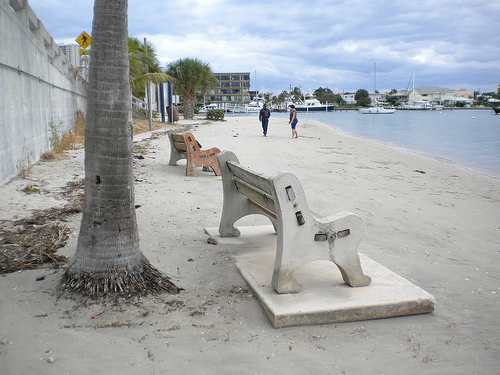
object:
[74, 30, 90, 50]
board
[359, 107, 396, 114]
boat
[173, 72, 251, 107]
building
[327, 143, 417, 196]
beach sand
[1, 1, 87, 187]
compound wall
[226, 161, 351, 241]
wood/concrete bench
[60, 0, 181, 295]
palm tree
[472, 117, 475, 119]
white buoy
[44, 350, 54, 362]
rock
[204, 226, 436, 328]
white base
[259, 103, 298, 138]
people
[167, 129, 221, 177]
bench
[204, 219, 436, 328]
concrete slab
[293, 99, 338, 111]
blue/white boat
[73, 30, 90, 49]
street sign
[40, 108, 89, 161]
dry/brown weeds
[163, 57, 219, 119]
palm trees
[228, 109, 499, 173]
sea water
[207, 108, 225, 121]
green bush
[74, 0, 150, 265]
tree trunk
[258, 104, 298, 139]
couple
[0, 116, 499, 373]
beach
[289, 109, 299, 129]
suit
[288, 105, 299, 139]
woman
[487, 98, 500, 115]
boats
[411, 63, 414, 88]
pole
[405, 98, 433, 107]
boat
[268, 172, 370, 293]
bench side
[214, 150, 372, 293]
bench